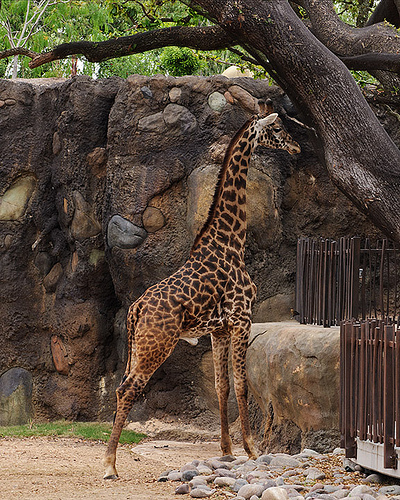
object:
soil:
[0, 437, 249, 499]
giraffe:
[101, 96, 302, 477]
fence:
[295, 236, 400, 331]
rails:
[350, 235, 361, 327]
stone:
[246, 317, 341, 452]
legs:
[102, 354, 160, 481]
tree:
[0, 0, 400, 241]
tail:
[112, 309, 134, 425]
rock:
[107, 215, 149, 252]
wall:
[0, 73, 399, 423]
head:
[254, 96, 301, 158]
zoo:
[0, 0, 397, 499]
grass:
[0, 416, 143, 443]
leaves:
[158, 47, 197, 74]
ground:
[0, 419, 399, 500]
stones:
[259, 484, 287, 499]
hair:
[190, 116, 256, 251]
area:
[101, 56, 273, 78]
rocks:
[142, 204, 167, 234]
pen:
[0, 79, 399, 426]